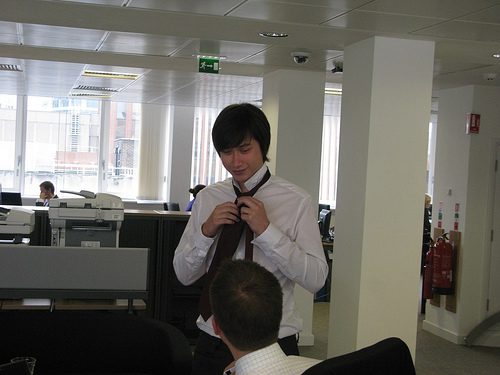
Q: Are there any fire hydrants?
A: Yes, there is a fire hydrant.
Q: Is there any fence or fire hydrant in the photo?
A: Yes, there is a fire hydrant.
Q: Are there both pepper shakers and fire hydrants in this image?
A: No, there is a fire hydrant but no pepper shakers.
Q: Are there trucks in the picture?
A: No, there are no trucks.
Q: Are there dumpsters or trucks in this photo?
A: No, there are no trucks or dumpsters.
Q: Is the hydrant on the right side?
A: Yes, the hydrant is on the right of the image.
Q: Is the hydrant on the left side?
A: No, the hydrant is on the right of the image.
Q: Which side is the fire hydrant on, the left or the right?
A: The fire hydrant is on the right of the image.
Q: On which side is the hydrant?
A: The hydrant is on the right of the image.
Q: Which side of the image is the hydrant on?
A: The hydrant is on the right of the image.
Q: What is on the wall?
A: The fire hydrant is on the wall.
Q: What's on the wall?
A: The fire hydrant is on the wall.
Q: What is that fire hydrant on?
A: The fire hydrant is on the wall.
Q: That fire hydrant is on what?
A: The fire hydrant is on the wall.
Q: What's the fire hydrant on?
A: The fire hydrant is on the wall.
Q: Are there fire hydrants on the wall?
A: Yes, there is a fire hydrant on the wall.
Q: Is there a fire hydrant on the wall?
A: Yes, there is a fire hydrant on the wall.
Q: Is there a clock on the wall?
A: No, there is a fire hydrant on the wall.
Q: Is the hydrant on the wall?
A: Yes, the hydrant is on the wall.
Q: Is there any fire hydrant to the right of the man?
A: Yes, there is a fire hydrant to the right of the man.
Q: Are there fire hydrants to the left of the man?
A: No, the fire hydrant is to the right of the man.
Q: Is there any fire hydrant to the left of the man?
A: No, the fire hydrant is to the right of the man.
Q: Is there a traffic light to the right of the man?
A: No, there is a fire hydrant to the right of the man.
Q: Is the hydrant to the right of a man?
A: Yes, the hydrant is to the right of a man.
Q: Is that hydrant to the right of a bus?
A: No, the hydrant is to the right of a man.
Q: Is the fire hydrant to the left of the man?
A: No, the fire hydrant is to the right of the man.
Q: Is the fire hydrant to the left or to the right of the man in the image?
A: The fire hydrant is to the right of the man.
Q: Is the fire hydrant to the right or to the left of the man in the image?
A: The fire hydrant is to the right of the man.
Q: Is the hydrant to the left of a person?
A: No, the hydrant is to the right of a person.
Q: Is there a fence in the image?
A: No, there are no fences.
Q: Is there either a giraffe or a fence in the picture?
A: No, there are no fences or giraffes.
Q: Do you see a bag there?
A: No, there are no bags.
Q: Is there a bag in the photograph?
A: No, there are no bags.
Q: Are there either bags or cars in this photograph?
A: No, there are no bags or cars.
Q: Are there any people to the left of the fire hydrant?
A: Yes, there is a person to the left of the fire hydrant.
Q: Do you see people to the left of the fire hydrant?
A: Yes, there is a person to the left of the fire hydrant.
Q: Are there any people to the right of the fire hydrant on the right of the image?
A: No, the person is to the left of the hydrant.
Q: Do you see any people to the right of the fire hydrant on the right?
A: No, the person is to the left of the hydrant.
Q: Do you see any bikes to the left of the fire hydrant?
A: No, there is a person to the left of the fire hydrant.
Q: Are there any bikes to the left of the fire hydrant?
A: No, there is a person to the left of the fire hydrant.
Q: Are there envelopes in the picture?
A: No, there are no envelopes.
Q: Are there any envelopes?
A: No, there are no envelopes.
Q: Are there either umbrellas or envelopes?
A: No, there are no envelopes or umbrellas.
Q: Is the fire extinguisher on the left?
A: No, the fire extinguisher is on the right of the image.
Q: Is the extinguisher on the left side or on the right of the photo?
A: The extinguisher is on the right of the image.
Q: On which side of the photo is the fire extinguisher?
A: The fire extinguisher is on the right of the image.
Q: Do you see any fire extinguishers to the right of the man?
A: Yes, there is a fire extinguisher to the right of the man.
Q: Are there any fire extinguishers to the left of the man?
A: No, the fire extinguisher is to the right of the man.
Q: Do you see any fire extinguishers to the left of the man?
A: No, the fire extinguisher is to the right of the man.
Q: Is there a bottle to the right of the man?
A: No, there is a fire extinguisher to the right of the man.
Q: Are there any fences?
A: No, there are no fences.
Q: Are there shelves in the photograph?
A: No, there are no shelves.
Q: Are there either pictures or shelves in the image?
A: No, there are no shelves or pictures.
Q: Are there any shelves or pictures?
A: No, there are no shelves or pictures.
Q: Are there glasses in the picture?
A: No, there are no glasses.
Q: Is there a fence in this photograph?
A: No, there are no fences.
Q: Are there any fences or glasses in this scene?
A: No, there are no fences or glasses.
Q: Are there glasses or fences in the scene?
A: No, there are no fences or glasses.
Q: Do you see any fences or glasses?
A: No, there are no fences or glasses.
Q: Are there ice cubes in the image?
A: No, there are no ice cubes.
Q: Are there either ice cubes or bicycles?
A: No, there are no ice cubes or bicycles.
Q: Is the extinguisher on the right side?
A: Yes, the extinguisher is on the right of the image.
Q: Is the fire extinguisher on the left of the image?
A: No, the fire extinguisher is on the right of the image.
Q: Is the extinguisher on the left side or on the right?
A: The extinguisher is on the right of the image.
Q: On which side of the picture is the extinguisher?
A: The extinguisher is on the right of the image.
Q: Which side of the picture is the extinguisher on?
A: The extinguisher is on the right of the image.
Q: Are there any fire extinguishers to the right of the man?
A: Yes, there is a fire extinguisher to the right of the man.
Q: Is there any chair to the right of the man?
A: No, there is a fire extinguisher to the right of the man.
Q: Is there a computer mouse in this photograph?
A: No, there are no computer mice.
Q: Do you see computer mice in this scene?
A: No, there are no computer mice.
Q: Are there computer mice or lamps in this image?
A: No, there are no computer mice or lamps.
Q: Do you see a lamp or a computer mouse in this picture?
A: No, there are no computer mice or lamps.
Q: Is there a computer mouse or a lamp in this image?
A: No, there are no computer mice or lamps.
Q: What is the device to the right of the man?
A: The device is a monitor.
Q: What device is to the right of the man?
A: The device is a monitor.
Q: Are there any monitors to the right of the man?
A: Yes, there is a monitor to the right of the man.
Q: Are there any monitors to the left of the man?
A: No, the monitor is to the right of the man.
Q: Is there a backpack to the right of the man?
A: No, there is a monitor to the right of the man.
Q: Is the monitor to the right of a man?
A: Yes, the monitor is to the right of a man.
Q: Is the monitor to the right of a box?
A: No, the monitor is to the right of a man.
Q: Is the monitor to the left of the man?
A: No, the monitor is to the right of the man.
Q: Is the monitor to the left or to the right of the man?
A: The monitor is to the right of the man.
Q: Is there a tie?
A: Yes, there is a tie.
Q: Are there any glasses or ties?
A: Yes, there is a tie.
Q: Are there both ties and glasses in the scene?
A: No, there is a tie but no glasses.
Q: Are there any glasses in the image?
A: No, there are no glasses.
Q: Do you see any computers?
A: Yes, there is a computer.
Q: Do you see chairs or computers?
A: Yes, there is a computer.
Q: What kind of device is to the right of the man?
A: The device is a computer.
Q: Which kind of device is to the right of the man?
A: The device is a computer.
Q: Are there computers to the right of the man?
A: Yes, there is a computer to the right of the man.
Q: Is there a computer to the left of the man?
A: No, the computer is to the right of the man.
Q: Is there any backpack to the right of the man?
A: No, there is a computer to the right of the man.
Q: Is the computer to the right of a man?
A: Yes, the computer is to the right of a man.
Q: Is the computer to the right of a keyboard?
A: No, the computer is to the right of a man.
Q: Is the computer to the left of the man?
A: No, the computer is to the right of the man.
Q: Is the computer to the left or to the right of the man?
A: The computer is to the right of the man.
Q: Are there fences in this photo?
A: No, there are no fences.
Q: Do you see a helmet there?
A: No, there are no helmets.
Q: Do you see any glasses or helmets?
A: No, there are no helmets or glasses.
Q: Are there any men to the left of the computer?
A: Yes, there is a man to the left of the computer.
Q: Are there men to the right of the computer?
A: No, the man is to the left of the computer.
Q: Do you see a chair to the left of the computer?
A: No, there is a man to the left of the computer.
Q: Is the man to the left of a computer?
A: Yes, the man is to the left of a computer.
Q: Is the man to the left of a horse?
A: No, the man is to the left of a computer.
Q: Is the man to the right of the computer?
A: No, the man is to the left of the computer.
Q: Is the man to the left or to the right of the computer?
A: The man is to the left of the computer.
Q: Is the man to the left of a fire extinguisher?
A: Yes, the man is to the left of a fire extinguisher.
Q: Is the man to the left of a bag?
A: No, the man is to the left of a fire extinguisher.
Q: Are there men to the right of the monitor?
A: No, the man is to the left of the monitor.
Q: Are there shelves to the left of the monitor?
A: No, there is a man to the left of the monitor.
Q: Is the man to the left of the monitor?
A: Yes, the man is to the left of the monitor.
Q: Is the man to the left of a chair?
A: No, the man is to the left of the monitor.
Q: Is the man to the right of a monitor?
A: No, the man is to the left of a monitor.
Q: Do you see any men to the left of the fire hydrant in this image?
A: Yes, there is a man to the left of the fire hydrant.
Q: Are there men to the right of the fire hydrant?
A: No, the man is to the left of the fire hydrant.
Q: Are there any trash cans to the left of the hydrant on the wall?
A: No, there is a man to the left of the fire hydrant.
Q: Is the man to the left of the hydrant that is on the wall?
A: Yes, the man is to the left of the fire hydrant.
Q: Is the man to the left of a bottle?
A: No, the man is to the left of the fire hydrant.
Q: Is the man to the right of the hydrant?
A: No, the man is to the left of the hydrant.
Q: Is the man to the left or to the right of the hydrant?
A: The man is to the left of the hydrant.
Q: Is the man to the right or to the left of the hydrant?
A: The man is to the left of the hydrant.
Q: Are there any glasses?
A: No, there are no glasses.